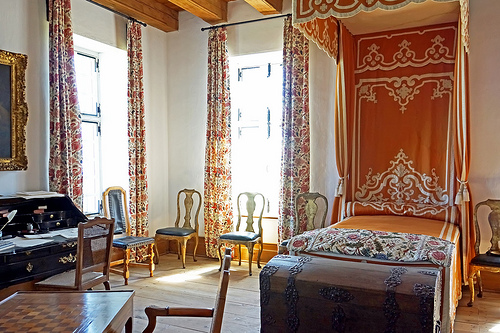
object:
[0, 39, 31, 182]
framed picture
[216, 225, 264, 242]
cushion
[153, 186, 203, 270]
chair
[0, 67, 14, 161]
painting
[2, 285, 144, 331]
board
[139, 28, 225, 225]
wall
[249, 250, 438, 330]
chest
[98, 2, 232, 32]
beams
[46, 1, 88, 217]
curtain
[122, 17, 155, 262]
curtain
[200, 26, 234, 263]
curtain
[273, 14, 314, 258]
curtain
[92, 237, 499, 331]
floor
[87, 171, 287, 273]
chairs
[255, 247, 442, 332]
trunk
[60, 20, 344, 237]
window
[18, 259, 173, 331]
chess board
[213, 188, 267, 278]
chair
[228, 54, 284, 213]
window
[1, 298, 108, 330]
board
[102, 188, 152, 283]
chair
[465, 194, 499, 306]
chair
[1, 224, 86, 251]
paper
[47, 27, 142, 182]
window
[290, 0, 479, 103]
canopy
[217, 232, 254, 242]
chair edge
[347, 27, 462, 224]
curtain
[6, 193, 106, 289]
desk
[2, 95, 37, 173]
picture frame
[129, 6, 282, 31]
beams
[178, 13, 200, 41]
ceiling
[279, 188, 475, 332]
bed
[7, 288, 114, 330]
chess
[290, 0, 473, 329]
canopy bed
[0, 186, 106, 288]
desk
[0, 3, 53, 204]
wall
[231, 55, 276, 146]
window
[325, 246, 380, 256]
edge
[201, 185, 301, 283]
chair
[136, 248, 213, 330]
floor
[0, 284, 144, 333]
table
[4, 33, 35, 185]
painting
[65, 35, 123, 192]
window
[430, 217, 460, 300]
edge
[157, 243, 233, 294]
sunshine